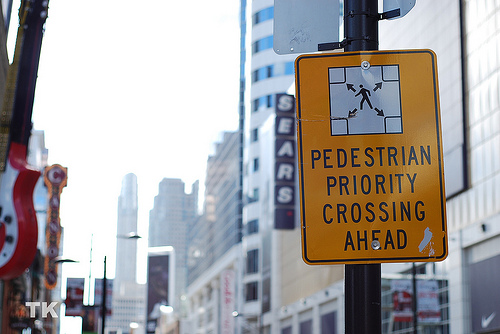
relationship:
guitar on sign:
[1, 0, 40, 282] [0, 0, 42, 282]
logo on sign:
[478, 312, 497, 328] [467, 252, 499, 333]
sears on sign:
[275, 94, 296, 206] [273, 92, 296, 230]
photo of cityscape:
[0, 0, 499, 331] [0, 0, 499, 333]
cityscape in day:
[0, 0, 499, 333] [1, 1, 500, 332]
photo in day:
[0, 0, 499, 331] [1, 1, 500, 332]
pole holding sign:
[343, 1, 381, 332] [295, 49, 449, 264]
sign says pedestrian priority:
[295, 49, 449, 264] [311, 146, 431, 196]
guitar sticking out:
[1, 0, 40, 282] [0, 0, 50, 278]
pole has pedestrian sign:
[343, 1, 381, 332] [295, 49, 449, 264]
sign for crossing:
[295, 49, 449, 264] [322, 200, 426, 223]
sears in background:
[275, 94, 296, 206] [47, 0, 497, 332]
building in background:
[240, 2, 355, 333] [47, 0, 497, 332]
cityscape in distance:
[0, 0, 499, 333] [0, 0, 498, 332]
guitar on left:
[1, 0, 40, 282] [0, 0, 50, 280]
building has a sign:
[240, 2, 355, 333] [273, 92, 296, 230]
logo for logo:
[480, 312, 498, 328] [478, 312, 497, 328]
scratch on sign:
[421, 226, 438, 259] [295, 49, 449, 264]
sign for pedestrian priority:
[295, 49, 449, 264] [311, 146, 431, 196]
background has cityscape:
[47, 0, 497, 332] [0, 0, 499, 333]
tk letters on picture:
[25, 301, 60, 319] [0, 0, 499, 331]